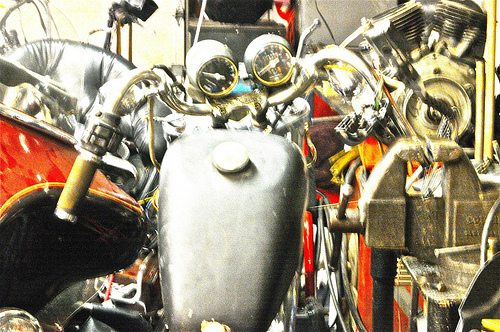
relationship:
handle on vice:
[322, 181, 363, 273] [328, 126, 499, 318]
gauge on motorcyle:
[178, 36, 232, 94] [161, 74, 416, 299]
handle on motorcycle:
[57, 153, 97, 223] [92, 52, 365, 328]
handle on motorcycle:
[57, 153, 97, 223] [36, 28, 423, 323]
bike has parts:
[0, 0, 500, 331] [104, 1, 172, 53]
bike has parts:
[0, 0, 500, 331] [1, 87, 131, 316]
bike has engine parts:
[0, 0, 500, 331] [339, 0, 498, 150]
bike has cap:
[0, 0, 500, 331] [213, 137, 256, 174]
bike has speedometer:
[0, 0, 500, 331] [243, 28, 295, 90]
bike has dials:
[0, 0, 500, 331] [197, 54, 237, 96]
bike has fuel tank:
[11, 3, 494, 331] [151, 100, 301, 327]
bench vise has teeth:
[357, 135, 498, 251] [394, 138, 463, 163]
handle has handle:
[57, 153, 97, 223] [58, 153, 98, 214]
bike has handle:
[0, 0, 500, 331] [57, 153, 97, 223]